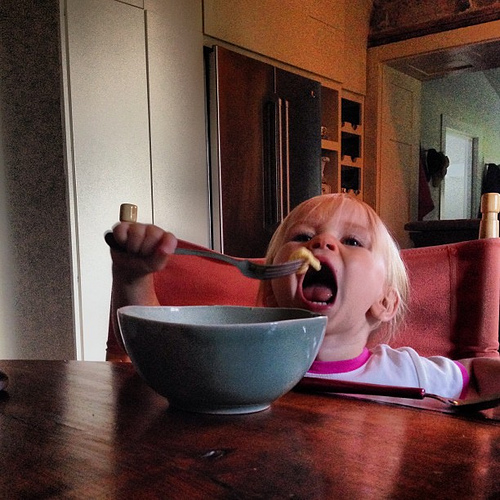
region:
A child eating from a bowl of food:
[90, 166, 483, 420]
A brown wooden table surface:
[3, 424, 493, 489]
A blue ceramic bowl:
[109, 296, 339, 419]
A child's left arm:
[412, 338, 497, 416]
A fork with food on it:
[166, 235, 322, 282]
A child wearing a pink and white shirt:
[259, 190, 496, 411]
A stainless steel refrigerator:
[201, 39, 325, 255]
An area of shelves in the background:
[321, 69, 374, 196]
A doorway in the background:
[434, 110, 487, 230]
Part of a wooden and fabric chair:
[411, 168, 498, 353]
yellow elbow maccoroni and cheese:
[288, 248, 321, 268]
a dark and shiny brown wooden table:
[0, 349, 498, 499]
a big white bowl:
[116, 302, 326, 419]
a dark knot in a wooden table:
[198, 443, 233, 460]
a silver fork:
[126, 220, 308, 285]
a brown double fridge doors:
[204, 40, 323, 250]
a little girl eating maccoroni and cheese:
[98, 191, 498, 403]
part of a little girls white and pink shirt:
[308, 342, 473, 402]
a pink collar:
[311, 350, 370, 372]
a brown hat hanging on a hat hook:
[421, 145, 449, 181]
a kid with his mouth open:
[206, 170, 427, 377]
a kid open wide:
[214, 180, 441, 394]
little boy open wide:
[228, 172, 421, 395]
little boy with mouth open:
[253, 183, 423, 363]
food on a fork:
[277, 239, 324, 280]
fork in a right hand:
[90, 211, 324, 284]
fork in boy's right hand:
[92, 208, 340, 293]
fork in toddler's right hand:
[97, 201, 333, 296]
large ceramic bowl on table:
[81, 277, 348, 442]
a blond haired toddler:
[210, 180, 433, 374]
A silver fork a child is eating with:
[103, 230, 308, 276]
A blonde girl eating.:
[109, 192, 499, 407]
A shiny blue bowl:
[114, 300, 326, 413]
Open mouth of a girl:
[298, 248, 338, 310]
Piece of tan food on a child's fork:
[289, 247, 321, 277]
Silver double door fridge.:
[207, 41, 324, 259]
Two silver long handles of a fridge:
[273, 95, 293, 230]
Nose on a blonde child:
[306, 226, 341, 253]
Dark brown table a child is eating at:
[0, 356, 499, 498]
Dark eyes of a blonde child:
[287, 231, 362, 246]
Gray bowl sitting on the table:
[115, 305, 326, 413]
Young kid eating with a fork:
[105, 190, 499, 402]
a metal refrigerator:
[209, 44, 322, 255]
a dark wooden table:
[0, 358, 499, 498]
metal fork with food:
[104, 223, 320, 280]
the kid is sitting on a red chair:
[104, 190, 499, 400]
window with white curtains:
[441, 115, 481, 219]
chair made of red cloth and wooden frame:
[105, 192, 499, 361]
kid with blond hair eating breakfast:
[108, 191, 498, 402]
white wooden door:
[377, 65, 420, 251]